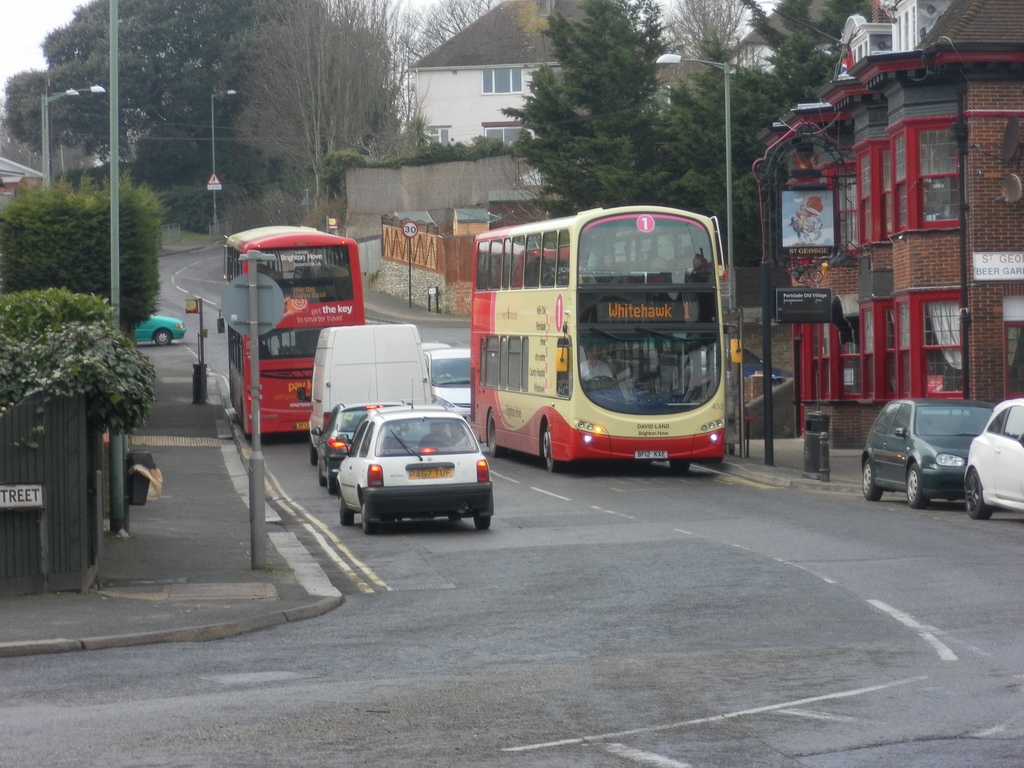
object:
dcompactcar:
[336, 412, 495, 534]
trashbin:
[803, 410, 830, 480]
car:
[964, 396, 1024, 518]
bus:
[469, 206, 726, 474]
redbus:
[224, 226, 366, 433]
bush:
[0, 173, 154, 320]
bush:
[0, 289, 156, 438]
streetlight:
[107, 0, 121, 354]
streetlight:
[655, 54, 748, 458]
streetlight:
[211, 89, 238, 241]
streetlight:
[41, 84, 106, 192]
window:
[918, 129, 957, 175]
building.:
[753, 0, 1022, 451]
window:
[922, 174, 960, 222]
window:
[923, 300, 962, 345]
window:
[923, 347, 962, 395]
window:
[896, 301, 909, 348]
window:
[900, 349, 911, 392]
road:
[0, 237, 1024, 768]